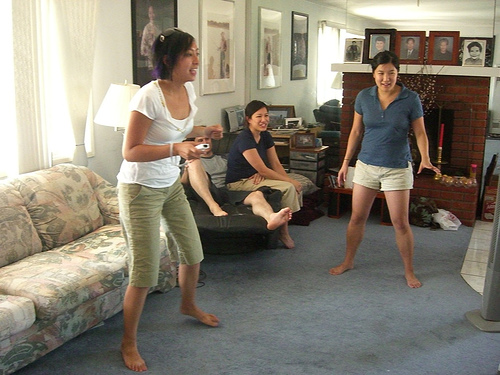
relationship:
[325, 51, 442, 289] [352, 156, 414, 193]
girl wearing shorts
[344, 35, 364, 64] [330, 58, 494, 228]
picture above fireplace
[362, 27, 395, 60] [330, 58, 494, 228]
picture above fireplace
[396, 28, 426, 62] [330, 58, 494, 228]
picture above fireplace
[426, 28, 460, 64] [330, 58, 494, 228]
picture above fireplace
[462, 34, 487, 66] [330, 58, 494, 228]
picture above fireplace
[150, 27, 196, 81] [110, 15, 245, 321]
dark hair on girl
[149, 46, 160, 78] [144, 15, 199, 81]
streak in hair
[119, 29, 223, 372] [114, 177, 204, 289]
girl wearing pants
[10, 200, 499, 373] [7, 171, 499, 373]
carpet on floor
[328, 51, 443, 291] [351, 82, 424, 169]
girl wearing blue shirt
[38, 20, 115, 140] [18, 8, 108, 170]
curtain on window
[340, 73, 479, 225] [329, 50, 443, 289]
fireplace behind woman